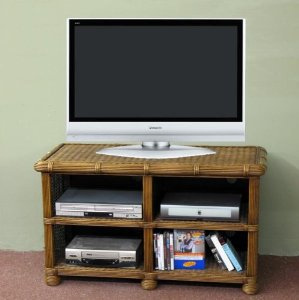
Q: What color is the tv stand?
A: Brown.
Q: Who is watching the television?
A: No one, the tv is off.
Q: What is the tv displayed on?
A: A tv stand.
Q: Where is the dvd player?
A: Bottom shelf.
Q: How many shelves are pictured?
A: Four.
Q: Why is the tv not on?
A: It is powered off.